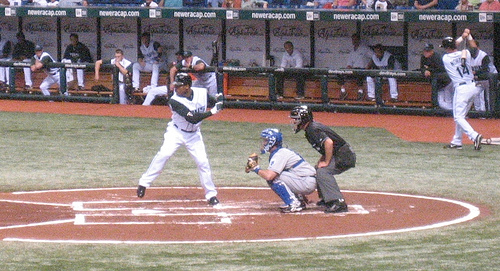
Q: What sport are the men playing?
A: Baseball.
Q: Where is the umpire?
A: Behind the catcher.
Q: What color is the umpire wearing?
A: Black.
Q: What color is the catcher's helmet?
A: Blue.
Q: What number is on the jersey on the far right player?
A: 14.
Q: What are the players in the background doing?
A: Sitting.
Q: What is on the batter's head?
A: Helmet.